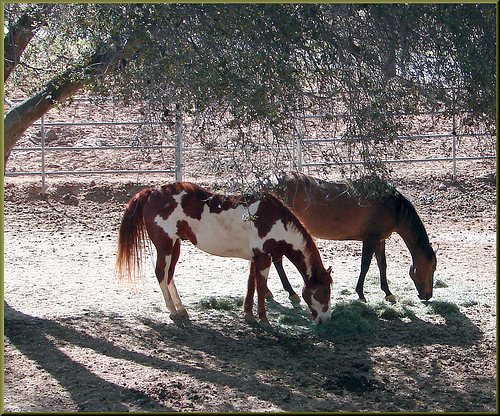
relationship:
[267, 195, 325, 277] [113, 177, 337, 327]
mane of horse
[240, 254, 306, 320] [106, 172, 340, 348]
legs of horse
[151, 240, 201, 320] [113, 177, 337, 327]
legs of horse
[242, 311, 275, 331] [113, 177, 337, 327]
hoof of horse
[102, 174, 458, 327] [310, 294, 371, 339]
horse eating hay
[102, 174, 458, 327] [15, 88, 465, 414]
horse in prairie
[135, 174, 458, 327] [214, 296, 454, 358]
horse eating grass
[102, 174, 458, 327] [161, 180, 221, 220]
horse with spots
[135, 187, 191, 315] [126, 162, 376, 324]
thigh of horse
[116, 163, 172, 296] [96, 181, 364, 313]
tail of horse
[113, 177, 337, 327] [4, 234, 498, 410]
horse grazing on grass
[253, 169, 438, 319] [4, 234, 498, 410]
horse grazing on grass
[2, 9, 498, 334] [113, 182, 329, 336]
tree shading horse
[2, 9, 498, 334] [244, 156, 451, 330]
tree shading horse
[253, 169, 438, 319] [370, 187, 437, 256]
horse with mane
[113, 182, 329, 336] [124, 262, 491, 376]
horse grazing on grass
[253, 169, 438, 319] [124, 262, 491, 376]
horse grazing on grass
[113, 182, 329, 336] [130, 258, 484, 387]
horse grazing on grass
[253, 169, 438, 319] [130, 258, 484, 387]
horse grazing on grass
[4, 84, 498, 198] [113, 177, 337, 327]
fence behind horse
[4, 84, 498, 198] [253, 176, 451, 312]
fence behind horse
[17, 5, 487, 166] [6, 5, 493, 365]
leaves of tree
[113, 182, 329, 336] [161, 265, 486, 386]
horse grazing on grass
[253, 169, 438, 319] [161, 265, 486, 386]
horse grazing on grass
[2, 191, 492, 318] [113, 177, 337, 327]
ground near horse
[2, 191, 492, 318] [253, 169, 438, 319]
ground near horse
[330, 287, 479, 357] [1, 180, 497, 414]
horse shadow near ground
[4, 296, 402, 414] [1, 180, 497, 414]
tree shadow near ground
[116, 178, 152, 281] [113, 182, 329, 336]
tail of horse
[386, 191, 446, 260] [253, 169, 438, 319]
mane of horse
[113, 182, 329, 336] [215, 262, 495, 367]
horse feeding on grass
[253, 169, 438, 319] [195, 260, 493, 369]
horse feeding on grass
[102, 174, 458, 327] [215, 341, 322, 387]
horse feeding on grass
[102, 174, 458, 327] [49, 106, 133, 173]
horse in an enclosure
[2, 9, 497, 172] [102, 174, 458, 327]
tree providing shade for horse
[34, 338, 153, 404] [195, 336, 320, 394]
shadow on ground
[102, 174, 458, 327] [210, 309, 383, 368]
horse feeding on grass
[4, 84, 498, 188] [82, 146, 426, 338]
fence near horses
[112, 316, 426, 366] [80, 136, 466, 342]
grass under horses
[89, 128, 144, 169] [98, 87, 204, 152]
dirt on far side of fence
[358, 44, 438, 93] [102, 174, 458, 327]
branch above horse